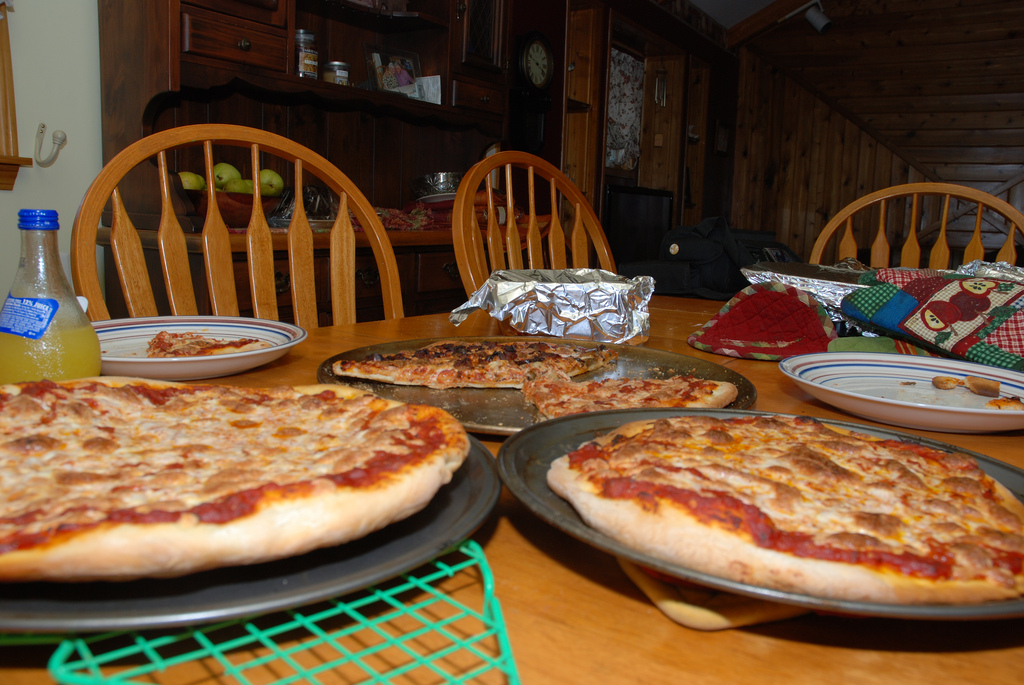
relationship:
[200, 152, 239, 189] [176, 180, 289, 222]
apple in bowl